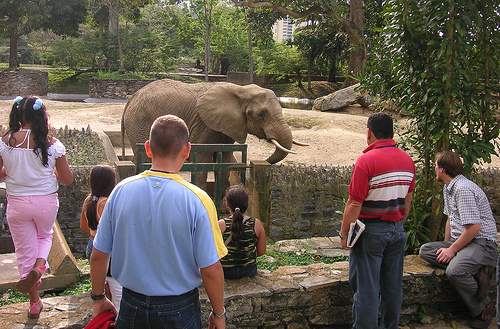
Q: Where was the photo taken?
A: It was taken at the zoo.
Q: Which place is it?
A: It is a zoo.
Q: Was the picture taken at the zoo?
A: Yes, it was taken in the zoo.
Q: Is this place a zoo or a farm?
A: It is a zoo.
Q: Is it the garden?
A: No, it is the zoo.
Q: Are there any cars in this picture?
A: No, there are no cars.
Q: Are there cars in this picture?
A: No, there are no cars.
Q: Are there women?
A: No, there are no women.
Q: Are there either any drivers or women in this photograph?
A: No, there are no women or drivers.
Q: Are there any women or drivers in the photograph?
A: No, there are no women or drivers.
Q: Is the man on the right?
A: Yes, the man is on the right of the image.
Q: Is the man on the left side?
A: No, the man is on the right of the image.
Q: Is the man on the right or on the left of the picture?
A: The man is on the right of the image.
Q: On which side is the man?
A: The man is on the right of the image.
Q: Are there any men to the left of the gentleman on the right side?
A: Yes, there is a man to the left of the gentleman.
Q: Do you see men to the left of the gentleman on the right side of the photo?
A: Yes, there is a man to the left of the gentleman.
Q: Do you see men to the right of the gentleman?
A: No, the man is to the left of the gentleman.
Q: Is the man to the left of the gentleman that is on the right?
A: Yes, the man is to the left of the gentleman.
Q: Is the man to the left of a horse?
A: No, the man is to the left of the gentleman.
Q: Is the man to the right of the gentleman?
A: No, the man is to the left of the gentleman.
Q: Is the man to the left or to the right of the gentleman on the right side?
A: The man is to the left of the gentleman.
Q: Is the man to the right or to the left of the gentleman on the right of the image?
A: The man is to the left of the gentleman.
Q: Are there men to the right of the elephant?
A: Yes, there is a man to the right of the elephant.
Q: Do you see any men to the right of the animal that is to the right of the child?
A: Yes, there is a man to the right of the elephant.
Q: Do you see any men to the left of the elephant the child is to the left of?
A: No, the man is to the right of the elephant.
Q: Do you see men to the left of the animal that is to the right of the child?
A: No, the man is to the right of the elephant.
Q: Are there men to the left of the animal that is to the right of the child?
A: No, the man is to the right of the elephant.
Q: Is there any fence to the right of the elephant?
A: No, there is a man to the right of the elephant.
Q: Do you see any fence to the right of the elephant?
A: No, there is a man to the right of the elephant.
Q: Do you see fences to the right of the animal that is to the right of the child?
A: No, there is a man to the right of the elephant.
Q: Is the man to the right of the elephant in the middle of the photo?
A: Yes, the man is to the right of the elephant.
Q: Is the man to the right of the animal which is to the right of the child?
A: Yes, the man is to the right of the elephant.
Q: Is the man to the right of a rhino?
A: No, the man is to the right of the elephant.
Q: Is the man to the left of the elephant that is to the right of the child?
A: No, the man is to the right of the elephant.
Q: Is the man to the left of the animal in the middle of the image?
A: No, the man is to the right of the elephant.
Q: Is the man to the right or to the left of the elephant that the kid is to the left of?
A: The man is to the right of the elephant.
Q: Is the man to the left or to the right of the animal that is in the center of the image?
A: The man is to the right of the elephant.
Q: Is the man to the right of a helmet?
A: No, the man is to the right of a child.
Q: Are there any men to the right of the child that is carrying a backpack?
A: Yes, there is a man to the right of the child.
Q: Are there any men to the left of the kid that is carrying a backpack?
A: No, the man is to the right of the child.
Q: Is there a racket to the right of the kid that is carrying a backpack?
A: No, there is a man to the right of the kid.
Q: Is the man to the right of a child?
A: Yes, the man is to the right of a child.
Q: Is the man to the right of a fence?
A: No, the man is to the right of a child.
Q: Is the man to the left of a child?
A: No, the man is to the right of a child.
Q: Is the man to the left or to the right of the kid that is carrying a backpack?
A: The man is to the right of the kid.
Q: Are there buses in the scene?
A: No, there are no buses.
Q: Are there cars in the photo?
A: No, there are no cars.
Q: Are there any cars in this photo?
A: No, there are no cars.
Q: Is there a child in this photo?
A: Yes, there is a child.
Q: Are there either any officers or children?
A: Yes, there is a child.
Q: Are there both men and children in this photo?
A: Yes, there are both a child and a man.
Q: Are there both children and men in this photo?
A: Yes, there are both a child and a man.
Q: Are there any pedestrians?
A: No, there are no pedestrians.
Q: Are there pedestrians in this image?
A: No, there are no pedestrians.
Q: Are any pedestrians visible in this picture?
A: No, there are no pedestrians.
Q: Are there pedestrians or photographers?
A: No, there are no pedestrians or photographers.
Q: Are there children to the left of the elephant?
A: Yes, there is a child to the left of the elephant.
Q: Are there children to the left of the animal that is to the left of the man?
A: Yes, there is a child to the left of the elephant.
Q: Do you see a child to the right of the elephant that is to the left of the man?
A: No, the child is to the left of the elephant.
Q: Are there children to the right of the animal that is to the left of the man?
A: No, the child is to the left of the elephant.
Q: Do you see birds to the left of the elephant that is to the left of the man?
A: No, there is a child to the left of the elephant.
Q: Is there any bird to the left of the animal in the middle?
A: No, there is a child to the left of the elephant.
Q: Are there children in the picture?
A: Yes, there is a child.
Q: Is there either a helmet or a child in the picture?
A: Yes, there is a child.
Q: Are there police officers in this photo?
A: No, there are no police officers.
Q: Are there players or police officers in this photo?
A: No, there are no police officers or players.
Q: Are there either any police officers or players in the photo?
A: No, there are no police officers or players.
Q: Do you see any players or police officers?
A: No, there are no police officers or players.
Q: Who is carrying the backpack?
A: The child is carrying the backpack.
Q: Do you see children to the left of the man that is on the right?
A: Yes, there is a child to the left of the man.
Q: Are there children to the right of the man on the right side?
A: No, the child is to the left of the man.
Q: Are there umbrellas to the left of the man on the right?
A: No, there is a child to the left of the man.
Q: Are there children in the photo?
A: Yes, there is a child.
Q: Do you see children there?
A: Yes, there is a child.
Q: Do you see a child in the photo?
A: Yes, there is a child.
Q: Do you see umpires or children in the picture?
A: Yes, there is a child.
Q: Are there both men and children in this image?
A: Yes, there are both a child and a man.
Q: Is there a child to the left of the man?
A: Yes, there is a child to the left of the man.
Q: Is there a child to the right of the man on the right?
A: No, the child is to the left of the man.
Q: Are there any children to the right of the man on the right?
A: No, the child is to the left of the man.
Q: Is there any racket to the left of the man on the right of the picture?
A: No, there is a child to the left of the man.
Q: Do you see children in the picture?
A: Yes, there is a child.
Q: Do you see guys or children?
A: Yes, there is a child.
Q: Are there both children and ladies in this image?
A: No, there is a child but no ladies.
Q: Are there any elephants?
A: Yes, there is an elephant.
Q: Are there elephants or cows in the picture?
A: Yes, there is an elephant.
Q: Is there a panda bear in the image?
A: No, there are no panda bears.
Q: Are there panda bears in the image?
A: No, there are no panda bears.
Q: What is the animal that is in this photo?
A: The animal is an elephant.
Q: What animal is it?
A: The animal is an elephant.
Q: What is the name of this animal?
A: This is an elephant.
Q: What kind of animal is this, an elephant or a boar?
A: This is an elephant.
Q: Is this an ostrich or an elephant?
A: This is an elephant.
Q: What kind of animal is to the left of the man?
A: The animal is an elephant.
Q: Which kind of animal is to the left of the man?
A: The animal is an elephant.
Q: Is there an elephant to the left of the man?
A: Yes, there is an elephant to the left of the man.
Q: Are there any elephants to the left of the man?
A: Yes, there is an elephant to the left of the man.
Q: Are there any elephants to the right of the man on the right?
A: No, the elephant is to the left of the man.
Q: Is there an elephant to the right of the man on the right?
A: No, the elephant is to the left of the man.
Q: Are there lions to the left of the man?
A: No, there is an elephant to the left of the man.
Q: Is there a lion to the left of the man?
A: No, there is an elephant to the left of the man.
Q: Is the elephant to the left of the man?
A: Yes, the elephant is to the left of the man.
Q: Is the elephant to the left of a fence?
A: No, the elephant is to the left of the man.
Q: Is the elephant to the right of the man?
A: No, the elephant is to the left of the man.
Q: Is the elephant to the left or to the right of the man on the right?
A: The elephant is to the left of the man.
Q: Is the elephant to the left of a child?
A: No, the elephant is to the right of a child.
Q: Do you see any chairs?
A: No, there are no chairs.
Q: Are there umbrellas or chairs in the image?
A: No, there are no chairs or umbrellas.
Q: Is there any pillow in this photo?
A: No, there are no pillows.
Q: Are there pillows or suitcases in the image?
A: No, there are no pillows or suitcases.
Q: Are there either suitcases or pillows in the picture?
A: No, there are no pillows or suitcases.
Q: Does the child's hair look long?
A: Yes, the hair is long.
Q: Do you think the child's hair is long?
A: Yes, the hair is long.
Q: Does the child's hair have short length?
A: No, the hair is long.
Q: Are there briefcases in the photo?
A: No, there are no briefcases.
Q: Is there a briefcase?
A: No, there are no briefcases.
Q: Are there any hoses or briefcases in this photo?
A: No, there are no briefcases or hoses.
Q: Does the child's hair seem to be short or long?
A: The hair is long.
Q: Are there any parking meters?
A: No, there are no parking meters.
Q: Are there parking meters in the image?
A: No, there are no parking meters.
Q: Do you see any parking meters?
A: No, there are no parking meters.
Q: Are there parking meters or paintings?
A: No, there are no parking meters or paintings.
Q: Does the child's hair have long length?
A: Yes, the hair is long.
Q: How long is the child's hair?
A: The hair is long.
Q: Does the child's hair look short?
A: No, the hair is long.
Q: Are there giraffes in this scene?
A: No, there are no giraffes.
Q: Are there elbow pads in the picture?
A: No, there are no elbow pads.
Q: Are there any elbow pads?
A: No, there are no elbow pads.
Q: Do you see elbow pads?
A: No, there are no elbow pads.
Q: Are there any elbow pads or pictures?
A: No, there are no elbow pads or pictures.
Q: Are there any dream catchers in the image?
A: No, there are no dream catchers.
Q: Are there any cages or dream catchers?
A: No, there are no dream catchers or cages.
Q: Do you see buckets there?
A: No, there are no buckets.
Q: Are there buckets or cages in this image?
A: No, there are no buckets or cages.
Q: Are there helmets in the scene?
A: No, there are no helmets.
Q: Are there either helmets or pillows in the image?
A: No, there are no helmets or pillows.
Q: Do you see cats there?
A: No, there are no cats.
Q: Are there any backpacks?
A: Yes, there is a backpack.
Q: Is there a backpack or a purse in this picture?
A: Yes, there is a backpack.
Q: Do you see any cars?
A: No, there are no cars.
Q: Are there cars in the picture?
A: No, there are no cars.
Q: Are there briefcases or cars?
A: No, there are no cars or briefcases.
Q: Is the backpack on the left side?
A: Yes, the backpack is on the left of the image.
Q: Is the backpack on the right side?
A: No, the backpack is on the left of the image.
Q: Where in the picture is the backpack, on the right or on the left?
A: The backpack is on the left of the image.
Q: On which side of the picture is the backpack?
A: The backpack is on the left of the image.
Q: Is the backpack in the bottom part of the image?
A: Yes, the backpack is in the bottom of the image.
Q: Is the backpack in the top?
A: No, the backpack is in the bottom of the image.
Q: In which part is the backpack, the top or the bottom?
A: The backpack is in the bottom of the image.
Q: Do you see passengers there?
A: No, there are no passengers.